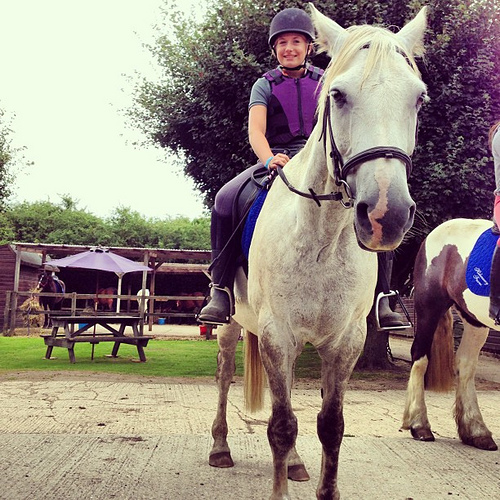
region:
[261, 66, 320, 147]
purple and black vest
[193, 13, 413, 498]
white and black horse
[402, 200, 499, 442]
white and brown horse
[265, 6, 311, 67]
black helmet rider is wearing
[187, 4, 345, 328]
woman riding a white horse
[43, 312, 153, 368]
picnic table in the grass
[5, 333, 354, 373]
grass patch behind the horses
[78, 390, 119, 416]
a crack in the cement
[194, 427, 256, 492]
a horses hoof on the ground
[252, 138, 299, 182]
a bracelet on a arm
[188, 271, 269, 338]
a boot in a stirup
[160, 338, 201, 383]
grass on the ground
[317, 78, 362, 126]
a eye on a horse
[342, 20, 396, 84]
hair on the horse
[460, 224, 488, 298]
a blue blanket on the horse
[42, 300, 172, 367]
a table on the grass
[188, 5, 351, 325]
woman wearing black helmet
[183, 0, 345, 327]
woman wearing black boots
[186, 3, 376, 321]
woman wearing gray t-shirt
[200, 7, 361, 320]
woman wearing purple vest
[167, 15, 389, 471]
woman riding a horse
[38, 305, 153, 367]
wooden picnic table with umbrella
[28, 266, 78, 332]
brown horse eating hay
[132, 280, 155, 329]
white horse in the stable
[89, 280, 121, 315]
brown horse in the stable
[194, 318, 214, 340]
red bucket by fence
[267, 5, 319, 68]
a black helmet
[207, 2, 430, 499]
a white horse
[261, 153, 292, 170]
the hand of a girl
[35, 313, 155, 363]
a wooden picnic table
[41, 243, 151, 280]
an outdoor table umbrella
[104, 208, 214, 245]
a section of green trees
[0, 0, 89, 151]
part of a sky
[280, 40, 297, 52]
the nose of a woman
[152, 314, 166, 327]
a blue bucket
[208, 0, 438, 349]
lady riding a horse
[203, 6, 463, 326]
lady riding a horse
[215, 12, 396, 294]
lady riding a horse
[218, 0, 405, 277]
lady riding a horse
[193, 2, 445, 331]
lady riding a horse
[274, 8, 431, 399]
the horse is white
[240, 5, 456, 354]
the horse is white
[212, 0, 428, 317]
the horse is white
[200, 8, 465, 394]
the horse is white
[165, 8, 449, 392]
the horse is white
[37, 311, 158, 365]
Small brown picknik table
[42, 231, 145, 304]
Large open black umbrella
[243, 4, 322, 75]
Black helmet on womans head